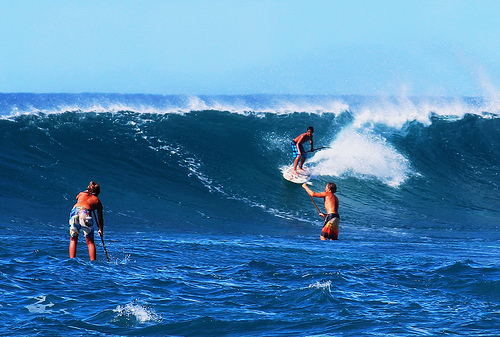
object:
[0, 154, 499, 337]
water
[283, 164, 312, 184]
board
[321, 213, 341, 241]
shorts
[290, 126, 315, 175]
guy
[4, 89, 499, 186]
wave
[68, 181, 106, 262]
guy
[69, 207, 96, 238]
swimming trunks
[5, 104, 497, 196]
big wave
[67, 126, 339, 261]
people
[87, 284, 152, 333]
wave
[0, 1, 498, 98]
blue sky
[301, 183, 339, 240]
guy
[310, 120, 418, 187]
splash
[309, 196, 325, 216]
paddle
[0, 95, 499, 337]
blue water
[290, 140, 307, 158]
swimming trunks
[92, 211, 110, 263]
paddle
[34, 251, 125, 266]
board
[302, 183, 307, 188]
hand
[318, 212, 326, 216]
hand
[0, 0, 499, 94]
clouds